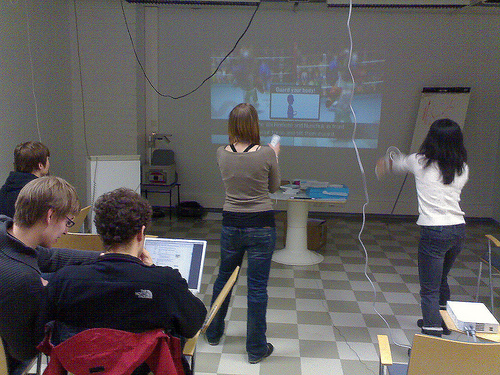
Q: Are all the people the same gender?
A: No, they are both male and female.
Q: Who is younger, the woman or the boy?
A: The boy is younger than the woman.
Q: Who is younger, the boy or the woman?
A: The boy is younger than the woman.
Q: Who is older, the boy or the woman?
A: The woman is older than the boy.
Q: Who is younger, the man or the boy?
A: The boy is younger than the man.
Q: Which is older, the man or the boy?
A: The man is older than the boy.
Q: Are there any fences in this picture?
A: No, there are no fences.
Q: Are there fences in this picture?
A: No, there are no fences.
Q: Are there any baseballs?
A: No, there are no baseballs.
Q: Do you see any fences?
A: No, there are no fences.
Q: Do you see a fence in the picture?
A: No, there are no fences.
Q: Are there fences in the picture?
A: No, there are no fences.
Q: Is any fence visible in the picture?
A: No, there are no fences.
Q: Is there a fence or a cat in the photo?
A: No, there are no fences or cats.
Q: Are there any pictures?
A: No, there are no pictures.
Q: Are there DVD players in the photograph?
A: No, there are no DVD players.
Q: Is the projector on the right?
A: Yes, the projector is on the right of the image.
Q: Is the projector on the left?
A: No, the projector is on the right of the image.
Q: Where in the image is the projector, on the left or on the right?
A: The projector is on the right of the image.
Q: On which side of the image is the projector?
A: The projector is on the right of the image.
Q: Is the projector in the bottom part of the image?
A: Yes, the projector is in the bottom of the image.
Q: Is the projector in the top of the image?
A: No, the projector is in the bottom of the image.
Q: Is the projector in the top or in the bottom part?
A: The projector is in the bottom of the image.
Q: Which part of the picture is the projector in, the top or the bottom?
A: The projector is in the bottom of the image.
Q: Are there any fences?
A: No, there are no fences.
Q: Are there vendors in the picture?
A: No, there are no vendors.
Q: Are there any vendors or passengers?
A: No, there are no vendors or passengers.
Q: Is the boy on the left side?
A: Yes, the boy is on the left of the image.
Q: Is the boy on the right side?
A: No, the boy is on the left of the image.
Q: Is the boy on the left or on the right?
A: The boy is on the left of the image.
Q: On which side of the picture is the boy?
A: The boy is on the left of the image.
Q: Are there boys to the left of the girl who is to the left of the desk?
A: Yes, there is a boy to the left of the girl.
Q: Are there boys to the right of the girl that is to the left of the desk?
A: No, the boy is to the left of the girl.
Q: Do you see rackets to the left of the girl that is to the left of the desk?
A: No, there is a boy to the left of the girl.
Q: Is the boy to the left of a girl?
A: Yes, the boy is to the left of a girl.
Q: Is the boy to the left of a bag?
A: No, the boy is to the left of a girl.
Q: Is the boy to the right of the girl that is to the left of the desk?
A: No, the boy is to the left of the girl.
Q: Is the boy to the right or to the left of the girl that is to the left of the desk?
A: The boy is to the left of the girl.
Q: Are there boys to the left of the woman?
A: Yes, there is a boy to the left of the woman.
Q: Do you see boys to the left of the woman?
A: Yes, there is a boy to the left of the woman.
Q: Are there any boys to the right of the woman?
A: No, the boy is to the left of the woman.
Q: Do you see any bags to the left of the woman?
A: No, there is a boy to the left of the woman.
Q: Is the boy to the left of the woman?
A: Yes, the boy is to the left of the woman.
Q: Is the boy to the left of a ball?
A: No, the boy is to the left of the woman.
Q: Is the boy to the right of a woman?
A: No, the boy is to the left of a woman.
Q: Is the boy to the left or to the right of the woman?
A: The boy is to the left of the woman.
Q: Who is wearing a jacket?
A: The boy is wearing a jacket.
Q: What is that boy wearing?
A: The boy is wearing a jacket.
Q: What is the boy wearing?
A: The boy is wearing a jacket.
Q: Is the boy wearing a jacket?
A: Yes, the boy is wearing a jacket.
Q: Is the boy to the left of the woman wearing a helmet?
A: No, the boy is wearing a jacket.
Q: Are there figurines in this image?
A: No, there are no figurines.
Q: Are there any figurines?
A: No, there are no figurines.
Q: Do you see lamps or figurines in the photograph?
A: No, there are no figurines or lamps.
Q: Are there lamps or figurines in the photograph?
A: No, there are no figurines or lamps.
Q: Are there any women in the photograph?
A: Yes, there is a woman.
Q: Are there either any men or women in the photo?
A: Yes, there is a woman.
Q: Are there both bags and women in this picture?
A: No, there is a woman but no bags.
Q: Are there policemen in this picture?
A: No, there are no policemen.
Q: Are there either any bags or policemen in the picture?
A: No, there are no policemen or bags.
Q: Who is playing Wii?
A: The woman is playing wii.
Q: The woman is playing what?
A: The woman is playing wii.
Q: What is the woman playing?
A: The woman is playing wii.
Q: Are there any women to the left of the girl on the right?
A: Yes, there is a woman to the left of the girl.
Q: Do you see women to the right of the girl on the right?
A: No, the woman is to the left of the girl.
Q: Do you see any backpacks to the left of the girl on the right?
A: No, there is a woman to the left of the girl.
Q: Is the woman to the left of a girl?
A: Yes, the woman is to the left of a girl.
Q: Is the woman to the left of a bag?
A: No, the woman is to the left of a girl.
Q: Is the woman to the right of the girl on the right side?
A: No, the woman is to the left of the girl.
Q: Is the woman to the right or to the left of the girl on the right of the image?
A: The woman is to the left of the girl.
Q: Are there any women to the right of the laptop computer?
A: Yes, there is a woman to the right of the laptop computer.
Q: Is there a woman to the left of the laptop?
A: No, the woman is to the right of the laptop.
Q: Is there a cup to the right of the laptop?
A: No, there is a woman to the right of the laptop.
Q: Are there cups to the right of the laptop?
A: No, there is a woman to the right of the laptop.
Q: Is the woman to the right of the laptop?
A: Yes, the woman is to the right of the laptop.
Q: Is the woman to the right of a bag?
A: No, the woman is to the right of the laptop.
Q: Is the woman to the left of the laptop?
A: No, the woman is to the right of the laptop.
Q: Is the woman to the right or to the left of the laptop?
A: The woman is to the right of the laptop.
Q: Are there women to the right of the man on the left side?
A: Yes, there is a woman to the right of the man.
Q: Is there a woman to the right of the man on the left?
A: Yes, there is a woman to the right of the man.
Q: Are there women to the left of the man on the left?
A: No, the woman is to the right of the man.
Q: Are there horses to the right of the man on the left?
A: No, there is a woman to the right of the man.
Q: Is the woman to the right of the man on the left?
A: Yes, the woman is to the right of the man.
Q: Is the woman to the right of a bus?
A: No, the woman is to the right of the man.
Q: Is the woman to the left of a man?
A: No, the woman is to the right of a man.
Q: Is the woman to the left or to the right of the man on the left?
A: The woman is to the right of the man.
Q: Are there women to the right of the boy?
A: Yes, there is a woman to the right of the boy.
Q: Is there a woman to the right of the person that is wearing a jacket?
A: Yes, there is a woman to the right of the boy.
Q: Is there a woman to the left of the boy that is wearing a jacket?
A: No, the woman is to the right of the boy.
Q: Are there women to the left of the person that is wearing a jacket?
A: No, the woman is to the right of the boy.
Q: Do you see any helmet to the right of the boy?
A: No, there is a woman to the right of the boy.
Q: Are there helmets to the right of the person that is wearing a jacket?
A: No, there is a woman to the right of the boy.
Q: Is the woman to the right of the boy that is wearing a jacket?
A: Yes, the woman is to the right of the boy.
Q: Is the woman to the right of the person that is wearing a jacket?
A: Yes, the woman is to the right of the boy.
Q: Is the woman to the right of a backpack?
A: No, the woman is to the right of the boy.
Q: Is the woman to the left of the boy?
A: No, the woman is to the right of the boy.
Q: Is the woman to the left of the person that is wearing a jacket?
A: No, the woman is to the right of the boy.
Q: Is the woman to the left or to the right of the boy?
A: The woman is to the right of the boy.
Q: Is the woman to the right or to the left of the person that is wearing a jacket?
A: The woman is to the right of the boy.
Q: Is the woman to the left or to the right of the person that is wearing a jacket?
A: The woman is to the right of the boy.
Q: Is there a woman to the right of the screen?
A: Yes, there is a woman to the right of the screen.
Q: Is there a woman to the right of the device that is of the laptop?
A: Yes, there is a woman to the right of the screen.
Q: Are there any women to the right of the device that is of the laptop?
A: Yes, there is a woman to the right of the screen.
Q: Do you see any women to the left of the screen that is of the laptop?
A: No, the woman is to the right of the screen.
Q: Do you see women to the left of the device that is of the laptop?
A: No, the woman is to the right of the screen.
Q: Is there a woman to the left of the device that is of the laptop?
A: No, the woman is to the right of the screen.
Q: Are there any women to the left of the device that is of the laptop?
A: No, the woman is to the right of the screen.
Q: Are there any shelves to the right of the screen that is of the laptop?
A: No, there is a woman to the right of the screen.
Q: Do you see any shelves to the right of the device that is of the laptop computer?
A: No, there is a woman to the right of the screen.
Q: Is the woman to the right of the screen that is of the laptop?
A: Yes, the woman is to the right of the screen.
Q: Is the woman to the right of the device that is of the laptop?
A: Yes, the woman is to the right of the screen.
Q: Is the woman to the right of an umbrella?
A: No, the woman is to the right of the screen.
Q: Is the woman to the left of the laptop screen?
A: No, the woman is to the right of the screen.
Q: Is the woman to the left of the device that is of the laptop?
A: No, the woman is to the right of the screen.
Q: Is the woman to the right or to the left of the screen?
A: The woman is to the right of the screen.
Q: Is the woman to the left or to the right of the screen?
A: The woman is to the right of the screen.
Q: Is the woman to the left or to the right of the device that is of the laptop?
A: The woman is to the right of the screen.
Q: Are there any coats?
A: Yes, there is a coat.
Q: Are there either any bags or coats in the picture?
A: Yes, there is a coat.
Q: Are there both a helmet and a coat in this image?
A: No, there is a coat but no helmets.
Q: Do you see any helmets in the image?
A: No, there are no helmets.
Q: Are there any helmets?
A: No, there are no helmets.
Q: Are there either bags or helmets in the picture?
A: No, there are no helmets or bags.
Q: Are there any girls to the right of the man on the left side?
A: Yes, there is a girl to the right of the man.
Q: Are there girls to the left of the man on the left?
A: No, the girl is to the right of the man.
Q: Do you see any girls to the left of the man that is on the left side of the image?
A: No, the girl is to the right of the man.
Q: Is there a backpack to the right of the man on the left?
A: No, there is a girl to the right of the man.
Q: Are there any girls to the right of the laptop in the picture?
A: Yes, there is a girl to the right of the laptop.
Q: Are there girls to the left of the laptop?
A: No, the girl is to the right of the laptop.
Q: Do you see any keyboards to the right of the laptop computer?
A: No, there is a girl to the right of the laptop computer.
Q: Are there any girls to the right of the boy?
A: Yes, there is a girl to the right of the boy.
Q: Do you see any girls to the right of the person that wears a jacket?
A: Yes, there is a girl to the right of the boy.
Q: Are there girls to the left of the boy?
A: No, the girl is to the right of the boy.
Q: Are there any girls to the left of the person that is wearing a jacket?
A: No, the girl is to the right of the boy.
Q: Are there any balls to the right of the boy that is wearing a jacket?
A: No, there is a girl to the right of the boy.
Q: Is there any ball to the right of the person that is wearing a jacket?
A: No, there is a girl to the right of the boy.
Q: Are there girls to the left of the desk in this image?
A: Yes, there is a girl to the left of the desk.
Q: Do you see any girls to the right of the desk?
A: No, the girl is to the left of the desk.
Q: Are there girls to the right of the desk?
A: No, the girl is to the left of the desk.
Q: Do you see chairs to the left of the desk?
A: No, there is a girl to the left of the desk.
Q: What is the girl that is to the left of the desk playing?
A: The girl is playing a video game.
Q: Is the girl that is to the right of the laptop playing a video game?
A: Yes, the girl is playing a video game.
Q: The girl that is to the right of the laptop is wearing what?
A: The girl is wearing jeans.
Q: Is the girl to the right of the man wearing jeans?
A: Yes, the girl is wearing jeans.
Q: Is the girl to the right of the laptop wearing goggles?
A: No, the girl is wearing jeans.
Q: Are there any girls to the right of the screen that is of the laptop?
A: Yes, there is a girl to the right of the screen.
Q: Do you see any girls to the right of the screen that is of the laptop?
A: Yes, there is a girl to the right of the screen.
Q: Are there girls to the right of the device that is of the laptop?
A: Yes, there is a girl to the right of the screen.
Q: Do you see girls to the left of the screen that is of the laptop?
A: No, the girl is to the right of the screen.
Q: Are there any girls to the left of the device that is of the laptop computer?
A: No, the girl is to the right of the screen.